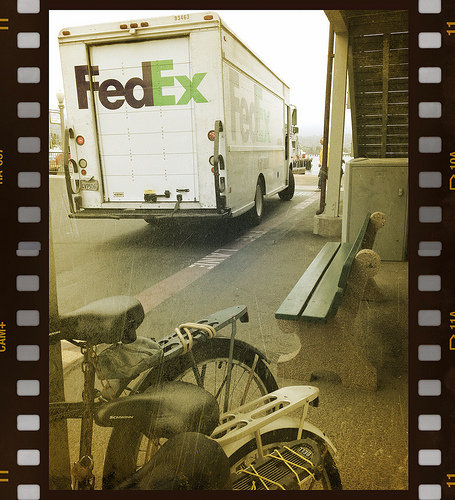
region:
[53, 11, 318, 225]
Truck is white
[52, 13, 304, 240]
Truck is closed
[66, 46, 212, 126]
Letter FedEx can be read on back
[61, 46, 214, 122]
Letters are black and green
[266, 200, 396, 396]
Bench is is green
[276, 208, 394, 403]
Support of bench is cement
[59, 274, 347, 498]
Two bikes can be seen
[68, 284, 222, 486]
Sits of bikes are black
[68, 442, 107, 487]
Lock on bike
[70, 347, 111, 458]
Chain on bike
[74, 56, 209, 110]
Fedex logo on the back of truck door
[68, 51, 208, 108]
fedex logo on a white truck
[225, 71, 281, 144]
Fedex logo on the side of the white truck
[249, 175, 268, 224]
black truck wheel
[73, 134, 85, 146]
red truck light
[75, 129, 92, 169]
red truck lights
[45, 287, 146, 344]
black bicycle seats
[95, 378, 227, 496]
two black bicycle seats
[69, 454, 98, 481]
lock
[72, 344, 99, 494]
bicycle chain and lock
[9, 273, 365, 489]
Two bicycles parked next to each other.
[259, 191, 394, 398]
Wood and stone bench.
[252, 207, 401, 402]
Nobody sitting on the bench.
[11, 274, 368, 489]
Nobody on the bicycles.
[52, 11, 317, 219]
One white FedEx truck.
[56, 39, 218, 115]
FedEx written on the truck.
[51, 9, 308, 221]
White delivery truck.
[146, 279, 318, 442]
Racks on the back of the bikes.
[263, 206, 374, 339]
The bench seat is green.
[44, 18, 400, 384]
Photo taken during the day.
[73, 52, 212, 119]
fedex written on the back of a truck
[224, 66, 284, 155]
fedex written on the right side of the truck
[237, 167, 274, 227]
right rear truck tire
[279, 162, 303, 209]
front right truck tire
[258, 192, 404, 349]
a green bench on the sidewalk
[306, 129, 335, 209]
a man standing behind a pole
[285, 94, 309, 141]
mirror on the right side of a truck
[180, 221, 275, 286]
the words "fire lane" written on the curb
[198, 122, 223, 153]
right turn signal on a truck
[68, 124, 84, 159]
left turn signal on a truck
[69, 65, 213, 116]
The FedEX logo multicolor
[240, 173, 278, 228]
Back wheel of truck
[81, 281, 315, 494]
A group of bikes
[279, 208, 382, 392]
A public sitting bench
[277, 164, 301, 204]
Front wheel of truck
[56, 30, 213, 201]
Back of delivery truck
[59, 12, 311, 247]
A large delivery truck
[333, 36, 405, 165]
The back of a stair well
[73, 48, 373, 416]
A truck leaving a building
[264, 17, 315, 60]
A white cloudy sky